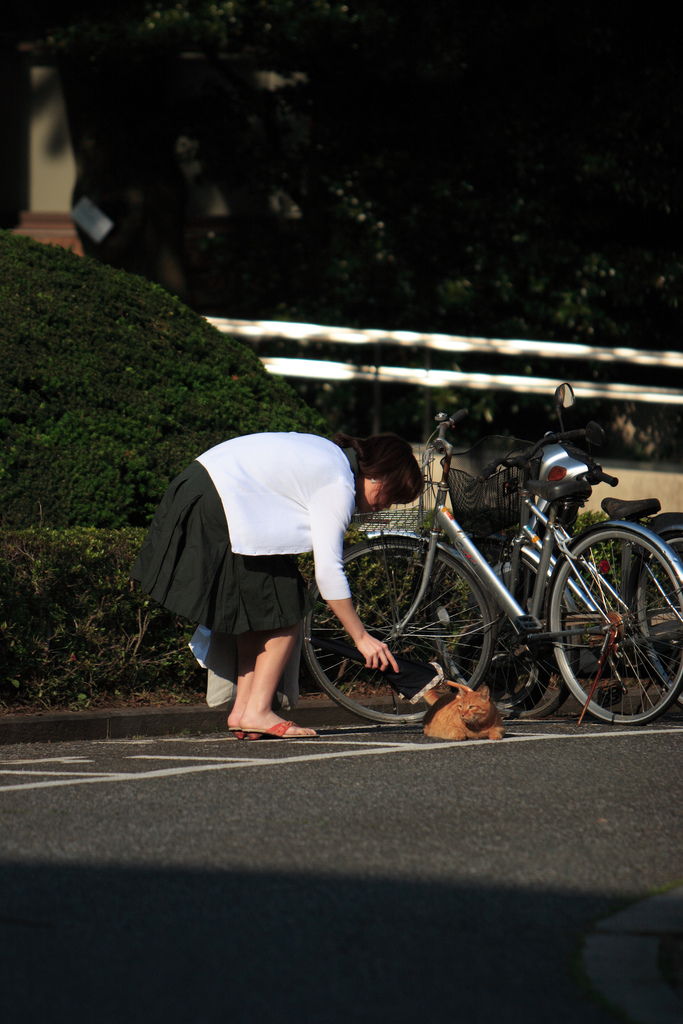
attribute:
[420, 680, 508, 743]
cat — one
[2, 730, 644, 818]
lines — white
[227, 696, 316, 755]
sandals — red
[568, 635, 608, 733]
kickstand — one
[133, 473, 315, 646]
skirt — black, flowy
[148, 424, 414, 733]
woman — one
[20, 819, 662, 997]
shadow — one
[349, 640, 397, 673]
hand — female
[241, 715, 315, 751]
foot — female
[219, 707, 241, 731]
foot — female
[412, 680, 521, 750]
cat — red, laying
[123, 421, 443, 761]
woman — bending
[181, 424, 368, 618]
cardigan — white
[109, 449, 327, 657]
skirt — black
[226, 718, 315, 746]
sandals — red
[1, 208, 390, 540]
bush — green, lush, round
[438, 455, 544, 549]
basket — black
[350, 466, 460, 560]
basket — silver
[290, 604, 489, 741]
umbrella — black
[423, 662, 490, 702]
handle — wooden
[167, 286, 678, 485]
fence — white, metal